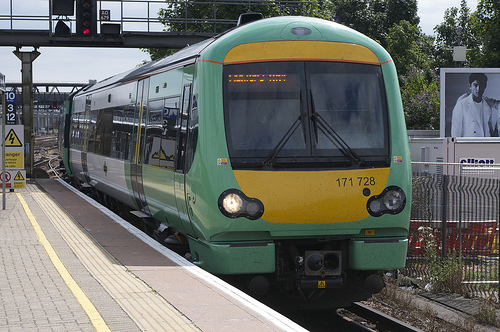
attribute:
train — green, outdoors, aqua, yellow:
[58, 15, 414, 310]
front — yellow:
[223, 39, 394, 221]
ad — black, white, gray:
[439, 66, 499, 137]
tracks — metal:
[325, 301, 422, 331]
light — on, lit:
[223, 192, 243, 212]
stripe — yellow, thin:
[14, 189, 112, 331]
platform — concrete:
[1, 176, 313, 330]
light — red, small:
[82, 27, 91, 36]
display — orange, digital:
[227, 72, 302, 90]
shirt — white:
[450, 94, 492, 137]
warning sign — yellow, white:
[3, 124, 28, 190]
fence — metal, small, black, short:
[411, 161, 499, 303]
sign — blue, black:
[4, 90, 18, 125]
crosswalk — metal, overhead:
[0, 0, 272, 47]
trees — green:
[150, 0, 499, 128]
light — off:
[383, 186, 402, 210]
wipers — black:
[261, 88, 361, 169]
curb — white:
[55, 174, 308, 331]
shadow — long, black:
[30, 172, 191, 268]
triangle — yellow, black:
[2, 129, 23, 148]